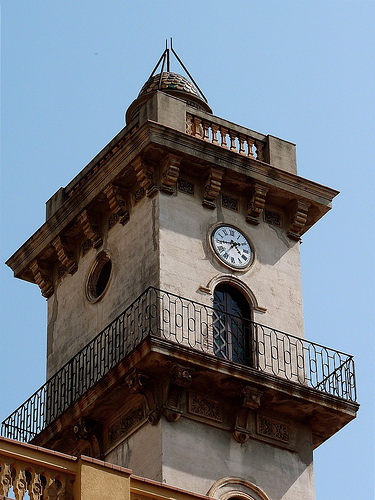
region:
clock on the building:
[198, 213, 266, 275]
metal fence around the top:
[1, 287, 372, 458]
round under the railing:
[212, 478, 302, 499]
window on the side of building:
[79, 248, 138, 305]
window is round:
[83, 260, 127, 305]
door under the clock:
[195, 266, 283, 370]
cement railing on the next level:
[2, 425, 197, 497]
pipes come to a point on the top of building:
[153, 25, 207, 86]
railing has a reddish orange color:
[8, 427, 168, 498]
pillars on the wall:
[189, 112, 272, 164]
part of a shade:
[253, 253, 294, 286]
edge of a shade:
[163, 457, 212, 490]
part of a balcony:
[285, 345, 298, 361]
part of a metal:
[305, 365, 323, 390]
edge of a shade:
[173, 465, 186, 477]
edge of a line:
[271, 369, 292, 390]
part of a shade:
[183, 458, 204, 475]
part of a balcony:
[323, 356, 344, 368]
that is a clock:
[210, 217, 253, 271]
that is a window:
[211, 278, 252, 371]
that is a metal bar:
[163, 293, 173, 342]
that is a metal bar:
[269, 326, 276, 380]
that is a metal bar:
[305, 340, 343, 350]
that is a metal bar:
[200, 303, 217, 310]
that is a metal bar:
[152, 290, 176, 299]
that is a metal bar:
[119, 305, 125, 319]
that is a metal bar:
[69, 341, 79, 367]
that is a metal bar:
[20, 382, 35, 408]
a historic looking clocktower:
[3, 31, 365, 497]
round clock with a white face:
[208, 214, 258, 272]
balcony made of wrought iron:
[147, 282, 358, 403]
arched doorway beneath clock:
[200, 271, 268, 368]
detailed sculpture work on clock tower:
[145, 360, 333, 439]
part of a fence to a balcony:
[3, 429, 172, 498]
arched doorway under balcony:
[197, 476, 273, 499]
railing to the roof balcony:
[151, 84, 298, 172]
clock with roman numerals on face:
[209, 214, 256, 270]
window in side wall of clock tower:
[79, 247, 117, 303]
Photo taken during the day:
[14, 13, 372, 485]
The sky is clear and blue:
[21, 6, 373, 420]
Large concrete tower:
[23, 53, 340, 490]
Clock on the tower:
[180, 207, 274, 279]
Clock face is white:
[191, 217, 270, 275]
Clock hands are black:
[202, 217, 258, 270]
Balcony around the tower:
[23, 295, 350, 460]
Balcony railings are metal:
[7, 317, 357, 409]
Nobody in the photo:
[0, 11, 357, 491]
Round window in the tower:
[77, 254, 121, 303]